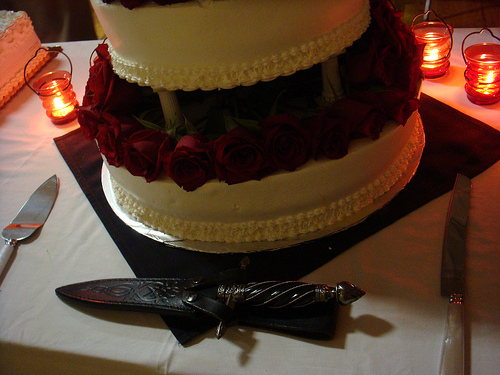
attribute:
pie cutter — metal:
[431, 168, 482, 374]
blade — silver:
[438, 169, 475, 302]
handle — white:
[435, 296, 471, 373]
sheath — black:
[49, 263, 248, 325]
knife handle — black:
[214, 256, 367, 342]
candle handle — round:
[19, 44, 74, 95]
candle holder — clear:
[30, 66, 81, 127]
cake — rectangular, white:
[0, 1, 65, 120]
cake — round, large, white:
[85, 1, 429, 259]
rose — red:
[161, 131, 213, 194]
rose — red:
[208, 123, 266, 185]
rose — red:
[254, 111, 310, 172]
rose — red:
[302, 107, 351, 165]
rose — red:
[328, 95, 383, 140]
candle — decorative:
[49, 93, 75, 122]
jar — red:
[16, 41, 85, 126]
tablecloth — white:
[2, 18, 495, 370]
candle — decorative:
[407, 7, 453, 82]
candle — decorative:
[462, 22, 496, 105]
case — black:
[51, 249, 275, 344]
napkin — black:
[36, 36, 494, 349]